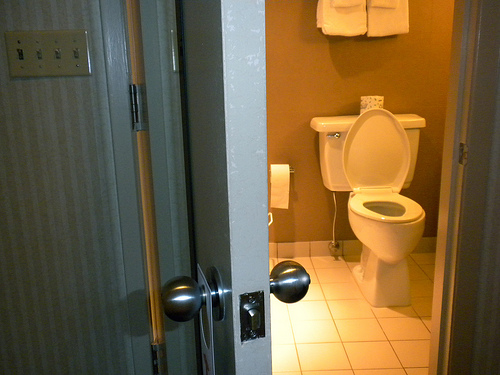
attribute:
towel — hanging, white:
[314, 2, 368, 39]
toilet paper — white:
[359, 93, 383, 117]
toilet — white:
[309, 112, 426, 307]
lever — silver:
[328, 133, 342, 140]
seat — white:
[347, 190, 424, 224]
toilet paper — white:
[269, 162, 292, 212]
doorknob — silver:
[272, 260, 311, 304]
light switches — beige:
[2, 28, 94, 82]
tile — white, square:
[297, 341, 354, 373]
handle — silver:
[327, 136, 341, 141]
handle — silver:
[158, 265, 226, 322]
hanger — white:
[196, 262, 213, 374]